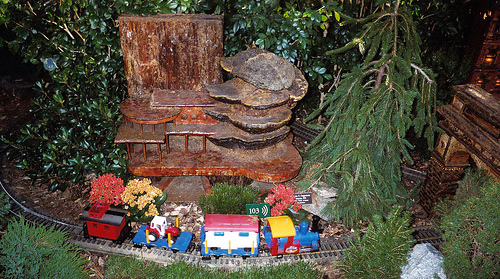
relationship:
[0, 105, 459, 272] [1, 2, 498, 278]
tracks through bushes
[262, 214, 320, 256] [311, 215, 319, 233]
engine with smokestack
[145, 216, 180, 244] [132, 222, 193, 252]
tractor on car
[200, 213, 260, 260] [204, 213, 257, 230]
car has roof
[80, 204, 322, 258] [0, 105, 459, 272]
train on tracks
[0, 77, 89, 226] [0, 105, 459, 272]
mulch near tracks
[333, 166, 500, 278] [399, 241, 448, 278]
bushes with rock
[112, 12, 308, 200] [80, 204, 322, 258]
decoration near train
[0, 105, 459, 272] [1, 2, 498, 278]
tracks by bushes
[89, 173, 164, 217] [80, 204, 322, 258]
flowers on train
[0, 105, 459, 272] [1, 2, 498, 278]
tracks near bushes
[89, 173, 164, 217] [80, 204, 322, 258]
flowers near train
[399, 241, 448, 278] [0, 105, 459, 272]
rock near tracks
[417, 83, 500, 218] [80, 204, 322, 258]
tunnel for train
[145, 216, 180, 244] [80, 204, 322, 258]
tractor on train